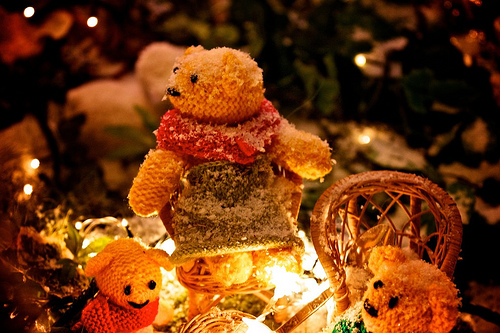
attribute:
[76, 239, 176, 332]
bear — yarn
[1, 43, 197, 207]
bear — white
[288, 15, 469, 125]
christmas tree — green, white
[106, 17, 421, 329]
bear — small, stuffed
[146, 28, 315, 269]
bear — small, yarn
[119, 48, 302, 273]
animal — white, crochet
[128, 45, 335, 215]
bear — sitting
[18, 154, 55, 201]
light bulbs — tiny, white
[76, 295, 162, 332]
scarf — red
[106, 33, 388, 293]
teddy bear — orange 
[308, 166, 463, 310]
chair — wicker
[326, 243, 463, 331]
bear — yarn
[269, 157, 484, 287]
chair — small, wicker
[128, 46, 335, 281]
bear — yarn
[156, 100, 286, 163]
scarf — red 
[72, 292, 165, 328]
scarf — orange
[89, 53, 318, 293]
bear — teddy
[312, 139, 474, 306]
chair — wicker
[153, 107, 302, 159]
scarf — stuffed animal's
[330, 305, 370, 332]
scarf — white, green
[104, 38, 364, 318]
bear — winter theme, display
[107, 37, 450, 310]
dolls — three, bear, group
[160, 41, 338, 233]
bear — doll, decoration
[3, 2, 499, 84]
lights — hanging lights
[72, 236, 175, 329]
bear — yarn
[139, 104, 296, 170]
scarf — red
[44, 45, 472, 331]
bears — yarn, display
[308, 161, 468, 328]
chair — tiny, wicker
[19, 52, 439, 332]
piece — decoration piece